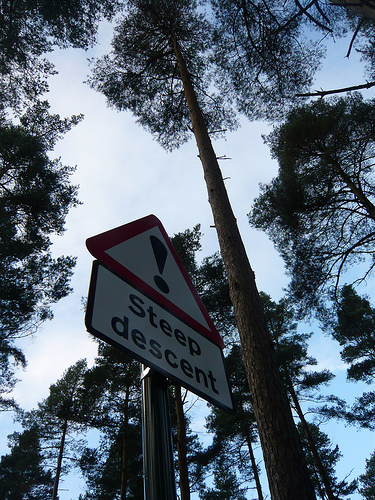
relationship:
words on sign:
[110, 290, 219, 395] [64, 195, 246, 413]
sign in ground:
[81, 214, 241, 411] [135, 436, 237, 493]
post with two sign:
[142, 365, 172, 494] [85, 264, 231, 411]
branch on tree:
[91, 45, 154, 113] [83, 2, 327, 277]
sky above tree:
[0, 6, 373, 497] [0, 200, 89, 347]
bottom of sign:
[117, 447, 164, 500] [81, 214, 241, 411]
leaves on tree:
[36, 419, 121, 500] [81, 2, 327, 498]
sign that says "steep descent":
[123, 351, 194, 450] [116, 316, 219, 378]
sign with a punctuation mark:
[85, 212, 224, 343] [145, 231, 172, 295]